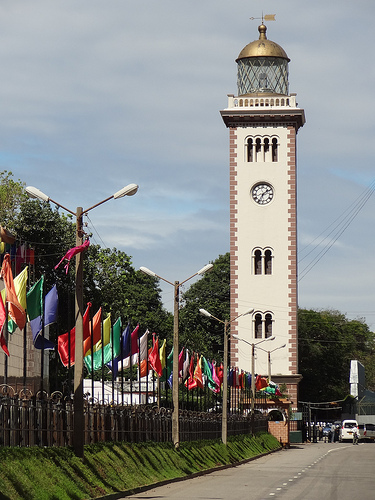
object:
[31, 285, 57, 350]
blueflag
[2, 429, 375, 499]
shadows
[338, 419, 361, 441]
van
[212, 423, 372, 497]
street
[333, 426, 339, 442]
people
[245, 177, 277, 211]
clock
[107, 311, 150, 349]
flag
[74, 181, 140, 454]
street light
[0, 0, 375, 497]
area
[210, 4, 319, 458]
building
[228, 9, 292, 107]
top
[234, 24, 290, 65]
dome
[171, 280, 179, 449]
pole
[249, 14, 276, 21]
weather vane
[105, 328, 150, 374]
white flag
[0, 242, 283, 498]
fence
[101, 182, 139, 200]
lights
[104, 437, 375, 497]
road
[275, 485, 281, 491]
line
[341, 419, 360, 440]
back end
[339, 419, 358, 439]
back